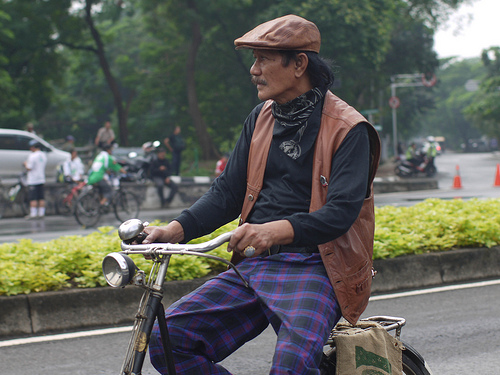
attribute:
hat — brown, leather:
[230, 10, 333, 58]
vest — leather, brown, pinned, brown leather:
[226, 97, 377, 309]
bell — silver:
[116, 216, 149, 246]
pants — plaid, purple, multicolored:
[150, 247, 351, 374]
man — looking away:
[132, 10, 394, 374]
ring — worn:
[244, 242, 256, 257]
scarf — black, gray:
[265, 83, 322, 162]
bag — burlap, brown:
[325, 318, 410, 372]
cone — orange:
[447, 158, 464, 191]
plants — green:
[2, 182, 500, 322]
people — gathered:
[25, 123, 242, 242]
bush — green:
[10, 198, 497, 269]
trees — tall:
[4, 2, 454, 190]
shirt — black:
[173, 103, 372, 256]